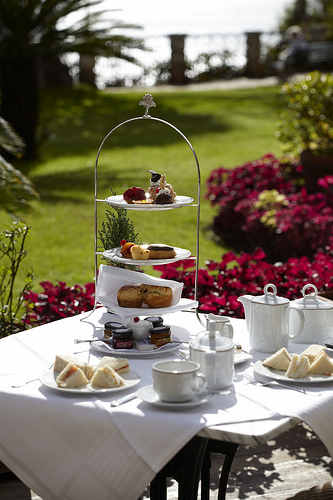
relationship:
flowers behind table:
[23, 150, 331, 321] [1, 302, 332, 449]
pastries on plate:
[123, 167, 173, 203] [106, 194, 193, 212]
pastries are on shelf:
[108, 176, 177, 359] [90, 321, 188, 356]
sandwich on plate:
[93, 363, 123, 386] [40, 368, 139, 391]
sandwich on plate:
[54, 362, 87, 386] [40, 368, 139, 391]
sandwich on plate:
[92, 354, 133, 373] [40, 368, 139, 391]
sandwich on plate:
[52, 354, 91, 373] [40, 368, 139, 391]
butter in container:
[134, 322, 148, 325] [127, 319, 152, 338]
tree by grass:
[27, 22, 110, 126] [105, 85, 278, 157]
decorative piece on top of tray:
[138, 93, 155, 115] [92, 90, 200, 318]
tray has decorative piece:
[92, 90, 200, 318] [138, 93, 155, 115]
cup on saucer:
[143, 355, 206, 403] [135, 384, 208, 411]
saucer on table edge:
[135, 384, 208, 411] [125, 412, 262, 454]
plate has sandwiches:
[32, 351, 145, 399] [52, 352, 131, 387]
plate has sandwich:
[252, 355, 331, 383] [262, 347, 291, 372]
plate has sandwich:
[252, 355, 331, 383] [283, 354, 309, 380]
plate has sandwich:
[252, 355, 331, 383] [308, 350, 332, 374]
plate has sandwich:
[252, 355, 331, 383] [300, 342, 327, 361]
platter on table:
[103, 194, 194, 214] [4, 286, 332, 498]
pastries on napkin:
[107, 279, 180, 308] [100, 256, 178, 305]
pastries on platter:
[121, 237, 175, 256] [97, 243, 190, 265]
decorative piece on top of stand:
[138, 93, 155, 115] [92, 91, 200, 311]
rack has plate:
[77, 91, 201, 356] [88, 335, 173, 356]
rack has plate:
[77, 91, 201, 356] [98, 295, 194, 313]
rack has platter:
[77, 91, 201, 356] [102, 243, 190, 265]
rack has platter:
[77, 91, 201, 356] [103, 194, 194, 214]